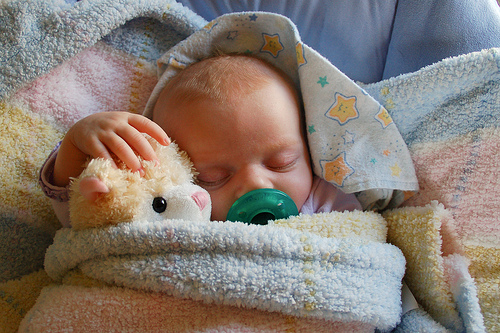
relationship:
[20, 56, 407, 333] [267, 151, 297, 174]
baby has eye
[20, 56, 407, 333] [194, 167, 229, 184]
baby has eye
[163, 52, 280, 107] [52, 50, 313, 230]
hair of baby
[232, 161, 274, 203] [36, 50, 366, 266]
nose of a baby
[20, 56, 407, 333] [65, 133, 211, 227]
baby holds bear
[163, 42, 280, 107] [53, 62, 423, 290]
hair on baby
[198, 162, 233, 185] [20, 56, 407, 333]
eye of baby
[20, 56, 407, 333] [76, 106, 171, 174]
baby has hand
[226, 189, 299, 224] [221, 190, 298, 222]
pacifier in mouth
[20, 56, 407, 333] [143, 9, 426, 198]
baby under blanket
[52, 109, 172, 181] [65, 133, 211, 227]
baby's hand on bear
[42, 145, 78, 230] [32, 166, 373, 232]
sleeve of gament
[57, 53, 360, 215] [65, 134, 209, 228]
baby with bear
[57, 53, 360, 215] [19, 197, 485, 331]
baby in blanket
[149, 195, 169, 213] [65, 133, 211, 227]
eye of bear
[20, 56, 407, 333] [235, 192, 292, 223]
baby with pacifier